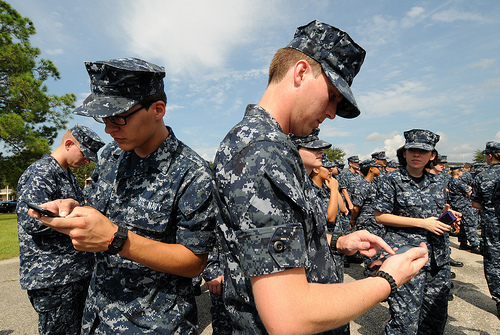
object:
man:
[16, 126, 103, 334]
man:
[475, 141, 500, 311]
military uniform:
[86, 126, 213, 333]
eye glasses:
[92, 99, 147, 128]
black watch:
[369, 270, 398, 296]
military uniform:
[15, 156, 83, 335]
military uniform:
[216, 102, 337, 335]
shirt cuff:
[233, 223, 313, 278]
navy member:
[371, 127, 463, 335]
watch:
[103, 225, 131, 255]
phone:
[385, 246, 419, 260]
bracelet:
[371, 270, 400, 299]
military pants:
[21, 283, 93, 333]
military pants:
[478, 224, 500, 313]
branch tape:
[139, 195, 163, 212]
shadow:
[451, 242, 488, 332]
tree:
[0, 0, 76, 184]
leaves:
[0, 0, 73, 157]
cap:
[289, 19, 363, 115]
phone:
[438, 209, 454, 224]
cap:
[72, 58, 164, 118]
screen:
[374, 245, 414, 264]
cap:
[400, 130, 442, 149]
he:
[30, 53, 220, 333]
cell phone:
[23, 202, 60, 223]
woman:
[307, 156, 349, 237]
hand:
[325, 176, 339, 187]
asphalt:
[342, 235, 499, 333]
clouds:
[12, 5, 499, 160]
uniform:
[372, 129, 463, 333]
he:
[212, 18, 425, 335]